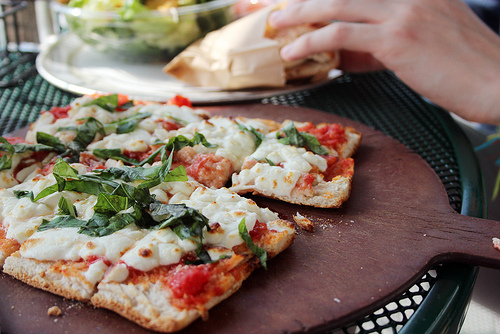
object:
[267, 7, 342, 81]
sandwich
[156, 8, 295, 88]
wrapper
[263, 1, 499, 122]
person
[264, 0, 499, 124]
hand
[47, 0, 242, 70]
bowl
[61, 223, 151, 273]
cheese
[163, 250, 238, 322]
tomato chunks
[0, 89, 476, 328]
board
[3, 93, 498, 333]
pizza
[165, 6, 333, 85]
bag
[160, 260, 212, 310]
tomato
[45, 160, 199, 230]
spinach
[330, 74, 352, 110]
ground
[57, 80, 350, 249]
square pizza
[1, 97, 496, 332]
tray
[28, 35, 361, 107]
dinner plate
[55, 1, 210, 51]
salad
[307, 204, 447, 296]
platter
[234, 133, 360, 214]
rectangular slice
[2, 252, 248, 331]
crust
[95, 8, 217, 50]
greens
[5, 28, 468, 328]
table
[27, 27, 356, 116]
plate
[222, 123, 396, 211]
bad sentence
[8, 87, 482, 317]
serving tray